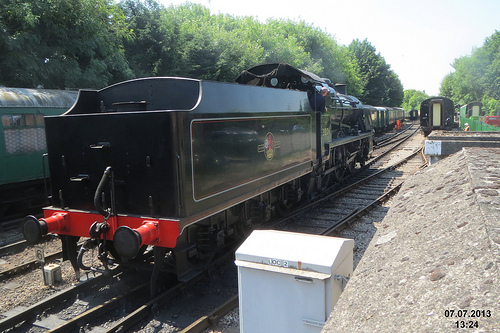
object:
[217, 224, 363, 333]
box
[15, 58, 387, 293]
train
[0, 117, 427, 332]
track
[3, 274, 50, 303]
stones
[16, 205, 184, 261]
bar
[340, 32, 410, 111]
tree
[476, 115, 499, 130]
truck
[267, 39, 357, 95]
smoke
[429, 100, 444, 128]
door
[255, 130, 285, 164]
logo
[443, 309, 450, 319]
numbers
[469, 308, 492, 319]
date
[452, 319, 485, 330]
writing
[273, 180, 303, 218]
wheel